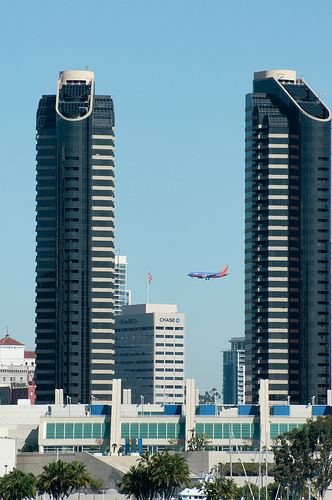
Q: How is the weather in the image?
A: It is clear.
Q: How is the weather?
A: It is clear.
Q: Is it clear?
A: Yes, it is clear.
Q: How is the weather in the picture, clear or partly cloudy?
A: It is clear.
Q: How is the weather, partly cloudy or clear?
A: It is clear.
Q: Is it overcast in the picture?
A: No, it is clear.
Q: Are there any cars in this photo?
A: No, there are no cars.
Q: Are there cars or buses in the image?
A: No, there are no cars or buses.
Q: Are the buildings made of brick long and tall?
A: Yes, the buildings are long and tall.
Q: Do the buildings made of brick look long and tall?
A: Yes, the buildings are long and tall.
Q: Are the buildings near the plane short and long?
A: No, the buildings are long but tall.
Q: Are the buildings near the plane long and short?
A: No, the buildings are long but tall.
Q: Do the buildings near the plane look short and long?
A: No, the buildings are long but tall.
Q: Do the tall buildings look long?
A: Yes, the buildings are long.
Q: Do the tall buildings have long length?
A: Yes, the buildings are long.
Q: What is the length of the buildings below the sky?
A: The buildings are long.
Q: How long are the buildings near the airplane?
A: The buildings are long.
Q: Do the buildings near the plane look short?
A: No, the buildings are long.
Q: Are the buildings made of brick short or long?
A: The buildings are long.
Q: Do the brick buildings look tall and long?
A: Yes, the buildings are tall and long.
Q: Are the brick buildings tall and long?
A: Yes, the buildings are tall and long.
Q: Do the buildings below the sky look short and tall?
A: No, the buildings are tall but long.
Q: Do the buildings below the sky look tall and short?
A: No, the buildings are tall but long.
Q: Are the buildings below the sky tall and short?
A: No, the buildings are tall but long.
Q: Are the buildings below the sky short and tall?
A: No, the buildings are tall but long.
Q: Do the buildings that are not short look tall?
A: Yes, the buildings are tall.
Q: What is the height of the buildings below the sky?
A: The buildings are tall.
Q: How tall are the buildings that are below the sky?
A: The buildings are tall.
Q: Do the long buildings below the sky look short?
A: No, the buildings are tall.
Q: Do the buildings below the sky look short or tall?
A: The buildings are tall.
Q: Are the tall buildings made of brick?
A: Yes, the buildings are made of brick.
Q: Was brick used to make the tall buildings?
A: Yes, the buildings are made of brick.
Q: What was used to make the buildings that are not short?
A: The buildings are made of brick.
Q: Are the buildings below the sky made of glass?
A: No, the buildings are made of brick.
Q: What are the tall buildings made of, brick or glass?
A: The buildings are made of brick.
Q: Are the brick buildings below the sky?
A: Yes, the buildings are below the sky.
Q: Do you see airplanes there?
A: Yes, there is an airplane.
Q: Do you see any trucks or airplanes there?
A: Yes, there is an airplane.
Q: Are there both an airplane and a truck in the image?
A: No, there is an airplane but no trucks.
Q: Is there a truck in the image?
A: No, there are no trucks.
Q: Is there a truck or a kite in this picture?
A: No, there are no trucks or kites.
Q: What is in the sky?
A: The airplane is in the sky.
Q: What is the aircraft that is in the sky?
A: The aircraft is an airplane.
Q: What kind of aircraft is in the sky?
A: The aircraft is an airplane.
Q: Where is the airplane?
A: The airplane is in the sky.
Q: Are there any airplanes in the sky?
A: Yes, there is an airplane in the sky.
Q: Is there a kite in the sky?
A: No, there is an airplane in the sky.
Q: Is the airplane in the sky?
A: Yes, the airplane is in the sky.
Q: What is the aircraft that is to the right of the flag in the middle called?
A: The aircraft is an airplane.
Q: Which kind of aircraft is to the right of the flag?
A: The aircraft is an airplane.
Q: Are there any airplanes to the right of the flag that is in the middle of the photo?
A: Yes, there is an airplane to the right of the flag.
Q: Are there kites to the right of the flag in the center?
A: No, there is an airplane to the right of the flag.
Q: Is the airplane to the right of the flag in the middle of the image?
A: Yes, the airplane is to the right of the flag.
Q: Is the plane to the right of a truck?
A: No, the plane is to the right of the flag.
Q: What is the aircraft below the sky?
A: The aircraft is an airplane.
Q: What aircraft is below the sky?
A: The aircraft is an airplane.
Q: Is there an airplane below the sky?
A: Yes, there is an airplane below the sky.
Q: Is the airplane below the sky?
A: Yes, the airplane is below the sky.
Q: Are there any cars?
A: No, there are no cars.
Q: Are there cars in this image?
A: No, there are no cars.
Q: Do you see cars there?
A: No, there are no cars.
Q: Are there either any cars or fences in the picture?
A: No, there are no cars or fences.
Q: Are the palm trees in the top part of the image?
A: No, the palm trees are in the bottom of the image.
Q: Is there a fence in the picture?
A: No, there are no fences.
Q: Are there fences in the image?
A: No, there are no fences.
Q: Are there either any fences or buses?
A: No, there are no fences or buses.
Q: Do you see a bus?
A: No, there are no buses.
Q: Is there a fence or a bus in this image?
A: No, there are no buses or fences.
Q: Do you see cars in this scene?
A: No, there are no cars.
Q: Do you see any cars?
A: No, there are no cars.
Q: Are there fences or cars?
A: No, there are no cars or fences.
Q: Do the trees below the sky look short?
A: Yes, the trees are short.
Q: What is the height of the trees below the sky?
A: The trees are short.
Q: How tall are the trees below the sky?
A: The trees are short.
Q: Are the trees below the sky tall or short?
A: The trees are short.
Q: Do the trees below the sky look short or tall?
A: The trees are short.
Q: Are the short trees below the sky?
A: Yes, the trees are below the sky.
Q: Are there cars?
A: No, there are no cars.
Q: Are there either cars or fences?
A: No, there are no cars or fences.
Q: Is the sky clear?
A: Yes, the sky is clear.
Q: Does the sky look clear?
A: Yes, the sky is clear.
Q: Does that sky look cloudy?
A: No, the sky is clear.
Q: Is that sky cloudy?
A: No, the sky is clear.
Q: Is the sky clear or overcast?
A: The sky is clear.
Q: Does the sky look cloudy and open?
A: No, the sky is open but clear.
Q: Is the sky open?
A: Yes, the sky is open.